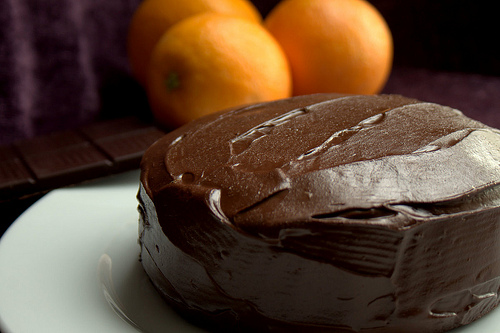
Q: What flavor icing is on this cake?
A: Chocolate.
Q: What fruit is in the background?
A: Oranges.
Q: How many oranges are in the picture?
A: Three.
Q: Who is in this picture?
A: No one.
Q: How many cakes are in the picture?
A: One.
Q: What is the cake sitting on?
A: Plate.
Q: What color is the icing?
A: Brown.